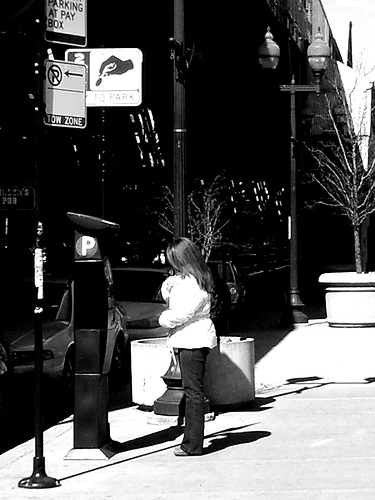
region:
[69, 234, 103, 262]
black and white writing on side of machine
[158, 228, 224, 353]
woman in white coat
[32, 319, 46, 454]
black and white metal pole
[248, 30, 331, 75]
black and white street lights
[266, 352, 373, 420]
shadow of street lights on ground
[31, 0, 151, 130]
black and white parking signs above road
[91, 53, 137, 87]
design on black and white sign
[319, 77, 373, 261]
black and white tree with no leaves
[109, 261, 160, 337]
black and white car parked beside road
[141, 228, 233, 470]
woman standing beside road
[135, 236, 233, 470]
a female on the street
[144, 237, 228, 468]
woman has long hair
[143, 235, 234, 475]
woman wears a white winter coat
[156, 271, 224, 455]
black pants under a white coat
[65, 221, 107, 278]
a parking sign on a pole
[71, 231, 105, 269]
letter P on a street sign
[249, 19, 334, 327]
pole has two lights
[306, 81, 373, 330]
a big pot with a tree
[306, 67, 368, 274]
tree in a pot without leaves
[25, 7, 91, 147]
two signs in a pole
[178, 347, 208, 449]
woman wears denim pants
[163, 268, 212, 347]
woman wears white jacket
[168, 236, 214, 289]
woman has long hair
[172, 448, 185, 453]
woman has closed toe shoes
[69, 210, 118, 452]
a P on the parking meter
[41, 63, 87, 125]
a tow zone sign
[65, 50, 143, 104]
a sign with a hand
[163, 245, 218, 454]
the lady is standing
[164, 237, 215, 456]
the woman is standing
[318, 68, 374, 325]
the tree is in a pot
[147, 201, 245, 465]
the girl is standing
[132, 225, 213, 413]
the girl is standing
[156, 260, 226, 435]
the girl is standing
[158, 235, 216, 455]
a woman standing on a sidewalk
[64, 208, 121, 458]
a black metal pay box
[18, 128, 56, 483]
a black metal pole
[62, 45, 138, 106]
a pay parking sign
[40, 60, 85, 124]
a no parking sign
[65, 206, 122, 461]
a parking pay box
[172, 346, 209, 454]
a woman's pair of jeans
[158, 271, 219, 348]
a woman's white coat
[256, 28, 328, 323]
a pole with two lights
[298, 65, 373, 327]
a tree in a big pot